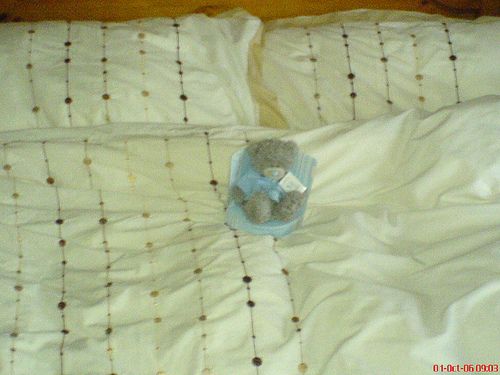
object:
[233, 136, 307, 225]
bear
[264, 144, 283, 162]
fur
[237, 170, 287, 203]
shirt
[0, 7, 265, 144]
pillow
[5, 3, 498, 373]
buscomforter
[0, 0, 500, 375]
bed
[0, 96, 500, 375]
blanket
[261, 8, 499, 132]
pillow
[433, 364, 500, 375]
letters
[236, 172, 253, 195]
arm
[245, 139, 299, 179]
head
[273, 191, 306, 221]
foot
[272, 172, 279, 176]
nose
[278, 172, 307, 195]
tag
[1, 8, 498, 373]
comforter